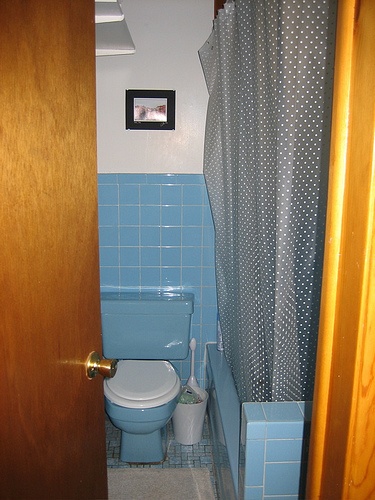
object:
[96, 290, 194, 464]
toilet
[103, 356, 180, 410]
lid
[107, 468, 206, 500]
mat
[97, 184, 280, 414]
floor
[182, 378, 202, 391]
container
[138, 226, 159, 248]
tile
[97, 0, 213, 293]
wall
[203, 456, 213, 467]
tile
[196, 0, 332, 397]
curtain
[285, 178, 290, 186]
polka dots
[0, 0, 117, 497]
door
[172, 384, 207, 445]
trash can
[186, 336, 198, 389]
brush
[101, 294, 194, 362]
tank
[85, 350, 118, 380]
knob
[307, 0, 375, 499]
frame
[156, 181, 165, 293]
grout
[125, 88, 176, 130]
picture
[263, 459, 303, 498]
tiles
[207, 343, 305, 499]
tub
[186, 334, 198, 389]
handle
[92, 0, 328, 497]
bathroom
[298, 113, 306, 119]
polka dot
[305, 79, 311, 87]
polka dot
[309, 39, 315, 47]
polka dot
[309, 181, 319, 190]
polka dot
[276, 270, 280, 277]
polka dot